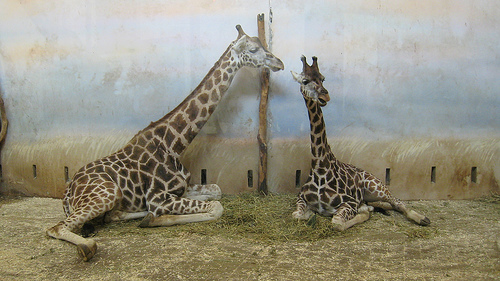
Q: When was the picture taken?
A: When the giraffes were sitting.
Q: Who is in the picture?
A: Giraffes.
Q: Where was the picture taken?
A: In a confined area.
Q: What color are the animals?
A: Brown and white.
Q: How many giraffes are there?
A: 2.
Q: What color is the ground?
A: Tan.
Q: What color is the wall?
A: Blue and brown.